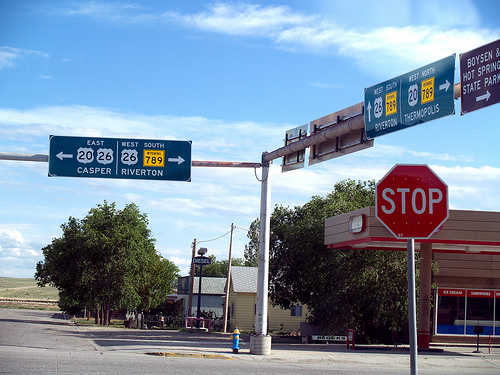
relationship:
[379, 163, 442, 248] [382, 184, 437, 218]
sign with white letters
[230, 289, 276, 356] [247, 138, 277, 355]
fire hydrant in front of pole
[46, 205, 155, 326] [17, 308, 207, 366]
trees near road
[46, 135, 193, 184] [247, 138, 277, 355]
sign on pole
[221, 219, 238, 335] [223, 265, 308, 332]
telephone pole near yellow house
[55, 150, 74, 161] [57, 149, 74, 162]
left points left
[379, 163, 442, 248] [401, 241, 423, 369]
stop sign on pole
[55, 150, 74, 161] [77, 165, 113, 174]
left for casper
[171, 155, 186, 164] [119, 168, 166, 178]
direction for riverton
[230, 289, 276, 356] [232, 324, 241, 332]
fire hydrant has yellow top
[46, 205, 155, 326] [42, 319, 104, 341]
trees near street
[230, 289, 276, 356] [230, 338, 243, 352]
fire hydrant has blue bottom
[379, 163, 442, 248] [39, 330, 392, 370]
sign at intersection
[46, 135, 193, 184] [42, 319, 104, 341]
sign above street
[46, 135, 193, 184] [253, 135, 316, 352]
sign on pole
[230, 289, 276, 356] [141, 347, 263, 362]
fire hydrant near curb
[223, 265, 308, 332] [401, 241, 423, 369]
yellow house near pole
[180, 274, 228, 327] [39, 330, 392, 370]
blue house near intersection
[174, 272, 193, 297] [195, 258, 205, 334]
sign on pole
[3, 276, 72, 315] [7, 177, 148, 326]
hill in background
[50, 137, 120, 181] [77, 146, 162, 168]
sign with numbers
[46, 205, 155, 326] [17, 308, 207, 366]
tree near road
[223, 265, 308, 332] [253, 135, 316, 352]
yellow house behind pole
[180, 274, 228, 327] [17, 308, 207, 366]
house near road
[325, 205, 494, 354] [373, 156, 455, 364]
store behind stop sign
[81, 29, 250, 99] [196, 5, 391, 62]
sky has no clouds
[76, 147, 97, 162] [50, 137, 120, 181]
number 20 on sign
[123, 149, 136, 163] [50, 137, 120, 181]
number 26 on sign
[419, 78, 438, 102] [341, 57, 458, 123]
number 789 on sign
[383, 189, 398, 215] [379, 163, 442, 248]
letter s on sign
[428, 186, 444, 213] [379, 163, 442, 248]
letter p on sign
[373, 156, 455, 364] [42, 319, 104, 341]
stop sign at street